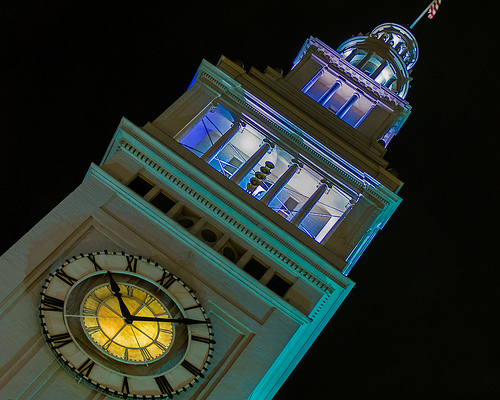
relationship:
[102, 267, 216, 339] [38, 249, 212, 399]
hands of clock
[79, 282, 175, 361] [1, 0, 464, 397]
face on side of building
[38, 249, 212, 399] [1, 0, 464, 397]
clock on side of building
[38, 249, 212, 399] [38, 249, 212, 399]
clock on clock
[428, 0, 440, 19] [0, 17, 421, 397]
flag on tower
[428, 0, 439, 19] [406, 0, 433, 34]
flag on pole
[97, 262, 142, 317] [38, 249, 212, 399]
hand on clock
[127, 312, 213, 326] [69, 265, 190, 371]
minute hand on clock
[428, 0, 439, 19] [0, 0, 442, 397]
flag on building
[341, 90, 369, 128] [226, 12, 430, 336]
light on tower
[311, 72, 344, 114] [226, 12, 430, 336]
light on tower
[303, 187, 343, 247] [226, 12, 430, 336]
light on tower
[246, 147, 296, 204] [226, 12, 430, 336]
light on tower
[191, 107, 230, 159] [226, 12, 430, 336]
light on tower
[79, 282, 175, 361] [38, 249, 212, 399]
face on clock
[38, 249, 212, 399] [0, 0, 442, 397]
clock on building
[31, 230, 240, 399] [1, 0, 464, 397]
clock on side of building